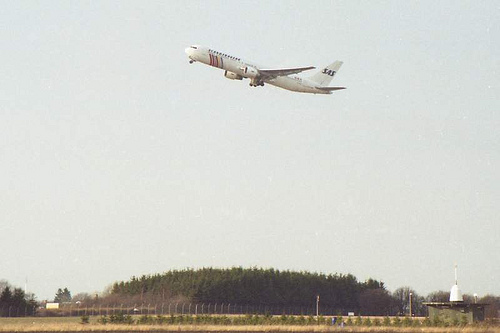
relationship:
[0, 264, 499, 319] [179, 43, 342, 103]
trees under airplane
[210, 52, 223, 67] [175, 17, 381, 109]
stripes on airplane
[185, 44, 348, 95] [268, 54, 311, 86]
airplane has wing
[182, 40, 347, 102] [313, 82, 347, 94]
airplane has wing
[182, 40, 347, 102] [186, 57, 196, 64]
airplane has wheel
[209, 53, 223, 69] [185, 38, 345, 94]
stripe on airplane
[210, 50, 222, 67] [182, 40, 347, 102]
stripe on airplane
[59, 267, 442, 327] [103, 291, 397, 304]
fence around airport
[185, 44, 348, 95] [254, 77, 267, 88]
airplane has landing gear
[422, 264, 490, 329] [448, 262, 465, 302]
building has white top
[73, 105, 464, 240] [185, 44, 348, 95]
gray sky with airplane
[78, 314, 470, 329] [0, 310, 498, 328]
bushes on runway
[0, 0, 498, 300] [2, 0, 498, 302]
clouds in sky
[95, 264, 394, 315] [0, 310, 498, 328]
trees beside runway